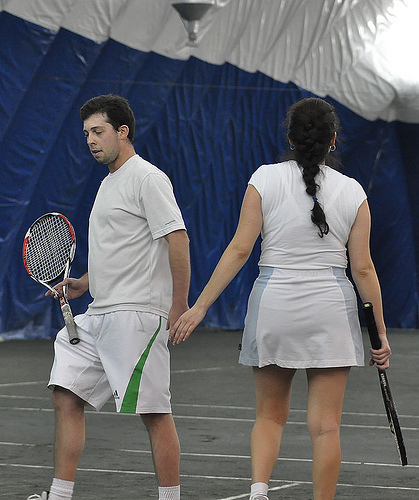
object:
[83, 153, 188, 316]
shirt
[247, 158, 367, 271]
shirt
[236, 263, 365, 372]
skirt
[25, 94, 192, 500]
man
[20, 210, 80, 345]
racket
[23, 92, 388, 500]
couple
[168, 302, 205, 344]
hands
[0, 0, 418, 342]
canopy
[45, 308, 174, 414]
shorts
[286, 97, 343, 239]
hair